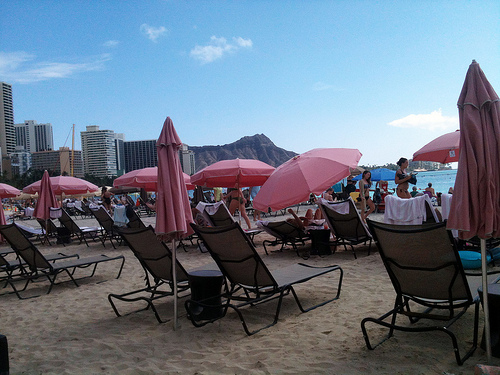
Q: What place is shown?
A: It is a beach.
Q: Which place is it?
A: It is a beach.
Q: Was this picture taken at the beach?
A: Yes, it was taken in the beach.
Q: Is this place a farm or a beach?
A: It is a beach.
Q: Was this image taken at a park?
A: No, the picture was taken in a beach.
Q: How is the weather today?
A: It is clear.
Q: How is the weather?
A: It is clear.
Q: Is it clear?
A: Yes, it is clear.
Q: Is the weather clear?
A: Yes, it is clear.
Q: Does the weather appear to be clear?
A: Yes, it is clear.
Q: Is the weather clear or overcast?
A: It is clear.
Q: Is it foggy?
A: No, it is clear.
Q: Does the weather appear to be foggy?
A: No, it is clear.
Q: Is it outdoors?
A: Yes, it is outdoors.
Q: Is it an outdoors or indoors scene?
A: It is outdoors.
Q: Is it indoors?
A: No, it is outdoors.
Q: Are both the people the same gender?
A: Yes, all the people are female.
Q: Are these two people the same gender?
A: Yes, all the people are female.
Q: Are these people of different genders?
A: No, all the people are female.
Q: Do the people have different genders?
A: No, all the people are female.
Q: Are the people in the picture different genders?
A: No, all the people are female.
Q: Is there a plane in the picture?
A: No, there are no airplanes.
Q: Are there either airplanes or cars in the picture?
A: No, there are no airplanes or cars.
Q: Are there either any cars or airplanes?
A: No, there are no airplanes or cars.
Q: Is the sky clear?
A: Yes, the sky is clear.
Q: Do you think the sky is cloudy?
A: No, the sky is clear.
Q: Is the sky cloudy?
A: No, the sky is clear.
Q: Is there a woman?
A: Yes, there is a woman.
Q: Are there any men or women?
A: Yes, there is a woman.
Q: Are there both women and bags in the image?
A: No, there is a woman but no bags.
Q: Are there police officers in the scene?
A: No, there are no police officers.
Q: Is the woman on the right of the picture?
A: Yes, the woman is on the right of the image.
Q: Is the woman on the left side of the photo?
A: No, the woman is on the right of the image.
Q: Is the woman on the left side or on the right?
A: The woman is on the right of the image.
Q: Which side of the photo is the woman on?
A: The woman is on the right of the image.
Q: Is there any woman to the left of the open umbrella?
A: No, the woman is to the right of the umbrella.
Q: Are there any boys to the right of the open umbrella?
A: No, there is a woman to the right of the umbrella.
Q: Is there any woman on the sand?
A: Yes, there is a woman on the sand.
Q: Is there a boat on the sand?
A: No, there is a woman on the sand.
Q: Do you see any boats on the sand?
A: No, there is a woman on the sand.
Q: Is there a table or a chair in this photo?
A: Yes, there is a chair.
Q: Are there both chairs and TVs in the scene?
A: No, there is a chair but no televisions.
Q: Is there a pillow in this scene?
A: No, there are no pillows.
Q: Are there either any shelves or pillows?
A: No, there are no pillows or shelves.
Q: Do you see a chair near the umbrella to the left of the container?
A: Yes, there is a chair near the umbrella.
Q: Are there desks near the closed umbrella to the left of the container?
A: No, there is a chair near the umbrella.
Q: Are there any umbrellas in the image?
A: Yes, there is an umbrella.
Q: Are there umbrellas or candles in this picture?
A: Yes, there is an umbrella.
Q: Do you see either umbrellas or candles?
A: Yes, there is an umbrella.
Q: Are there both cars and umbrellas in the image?
A: No, there is an umbrella but no cars.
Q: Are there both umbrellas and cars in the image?
A: No, there is an umbrella but no cars.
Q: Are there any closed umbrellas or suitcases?
A: Yes, there is a closed umbrella.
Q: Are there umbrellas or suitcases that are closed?
A: Yes, the umbrella is closed.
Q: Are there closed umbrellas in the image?
A: Yes, there is a closed umbrella.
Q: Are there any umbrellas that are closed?
A: Yes, there is an umbrella that is closed.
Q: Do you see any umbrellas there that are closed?
A: Yes, there is an umbrella that is closed.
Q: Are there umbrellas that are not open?
A: Yes, there is an closed umbrella.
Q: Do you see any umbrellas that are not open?
A: Yes, there is an closed umbrella.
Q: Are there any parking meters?
A: No, there are no parking meters.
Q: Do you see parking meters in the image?
A: No, there are no parking meters.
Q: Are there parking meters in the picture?
A: No, there are no parking meters.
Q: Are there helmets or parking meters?
A: No, there are no parking meters or helmets.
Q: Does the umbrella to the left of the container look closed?
A: Yes, the umbrella is closed.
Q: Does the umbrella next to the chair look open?
A: No, the umbrella is closed.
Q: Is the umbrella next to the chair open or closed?
A: The umbrella is closed.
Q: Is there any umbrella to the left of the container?
A: Yes, there is an umbrella to the left of the container.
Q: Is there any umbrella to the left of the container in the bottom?
A: Yes, there is an umbrella to the left of the container.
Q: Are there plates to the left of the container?
A: No, there is an umbrella to the left of the container.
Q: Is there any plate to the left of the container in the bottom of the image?
A: No, there is an umbrella to the left of the container.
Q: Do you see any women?
A: Yes, there is a woman.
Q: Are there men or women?
A: Yes, there is a woman.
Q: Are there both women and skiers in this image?
A: No, there is a woman but no skiers.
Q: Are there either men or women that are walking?
A: Yes, the woman is walking.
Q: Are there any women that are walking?
A: Yes, there is a woman that is walking.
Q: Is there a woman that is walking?
A: Yes, there is a woman that is walking.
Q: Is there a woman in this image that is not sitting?
A: Yes, there is a woman that is walking.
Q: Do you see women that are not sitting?
A: Yes, there is a woman that is walking .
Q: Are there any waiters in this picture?
A: No, there are no waiters.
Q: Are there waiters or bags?
A: No, there are no waiters or bags.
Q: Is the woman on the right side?
A: Yes, the woman is on the right of the image.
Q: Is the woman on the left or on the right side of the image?
A: The woman is on the right of the image.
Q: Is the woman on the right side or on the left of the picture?
A: The woman is on the right of the image.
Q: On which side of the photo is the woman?
A: The woman is on the right of the image.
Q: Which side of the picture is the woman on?
A: The woman is on the right of the image.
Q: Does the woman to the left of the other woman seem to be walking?
A: Yes, the woman is walking.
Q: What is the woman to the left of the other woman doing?
A: The woman is walking.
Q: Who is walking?
A: The woman is walking.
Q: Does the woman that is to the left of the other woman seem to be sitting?
A: No, the woman is walking.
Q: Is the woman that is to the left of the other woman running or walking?
A: The woman is walking.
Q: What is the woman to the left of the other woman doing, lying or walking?
A: The woman is walking.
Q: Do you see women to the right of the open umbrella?
A: Yes, there is a woman to the right of the umbrella.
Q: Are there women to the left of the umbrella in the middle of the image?
A: No, the woman is to the right of the umbrella.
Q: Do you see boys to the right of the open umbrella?
A: No, there is a woman to the right of the umbrella.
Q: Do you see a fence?
A: No, there are no fences.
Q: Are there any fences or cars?
A: No, there are no fences or cars.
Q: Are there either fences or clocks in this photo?
A: No, there are no clocks or fences.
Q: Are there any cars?
A: No, there are no cars.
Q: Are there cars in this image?
A: No, there are no cars.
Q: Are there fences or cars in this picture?
A: No, there are no cars or fences.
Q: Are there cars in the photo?
A: No, there are no cars.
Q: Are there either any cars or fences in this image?
A: No, there are no cars or fences.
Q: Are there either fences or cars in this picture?
A: No, there are no cars or fences.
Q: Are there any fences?
A: No, there are no fences.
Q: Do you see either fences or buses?
A: No, there are no fences or buses.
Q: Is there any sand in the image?
A: Yes, there is sand.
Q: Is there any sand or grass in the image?
A: Yes, there is sand.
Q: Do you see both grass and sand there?
A: No, there is sand but no grass.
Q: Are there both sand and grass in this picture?
A: No, there is sand but no grass.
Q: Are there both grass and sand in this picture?
A: No, there is sand but no grass.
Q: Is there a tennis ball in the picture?
A: No, there are no tennis balls.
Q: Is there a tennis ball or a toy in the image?
A: No, there are no tennis balls or toys.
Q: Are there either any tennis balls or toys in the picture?
A: No, there are no tennis balls or toys.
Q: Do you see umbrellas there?
A: Yes, there is an umbrella.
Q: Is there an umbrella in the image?
A: Yes, there is an umbrella.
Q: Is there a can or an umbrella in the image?
A: Yes, there is an umbrella.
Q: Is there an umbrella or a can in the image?
A: Yes, there is an umbrella.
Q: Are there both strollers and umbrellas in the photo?
A: No, there is an umbrella but no strollers.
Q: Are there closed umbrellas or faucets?
A: Yes, there is a closed umbrella.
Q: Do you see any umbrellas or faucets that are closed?
A: Yes, the umbrella is closed.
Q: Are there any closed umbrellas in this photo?
A: Yes, there is a closed umbrella.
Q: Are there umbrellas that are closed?
A: Yes, there is an umbrella that is closed.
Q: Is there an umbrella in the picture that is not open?
A: Yes, there is an closed umbrella.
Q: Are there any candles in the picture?
A: No, there are no candles.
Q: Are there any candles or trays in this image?
A: No, there are no candles or trays.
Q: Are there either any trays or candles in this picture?
A: No, there are no candles or trays.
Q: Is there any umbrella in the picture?
A: Yes, there is an umbrella.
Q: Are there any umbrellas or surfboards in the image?
A: Yes, there is an umbrella.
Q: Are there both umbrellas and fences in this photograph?
A: No, there is an umbrella but no fences.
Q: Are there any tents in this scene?
A: No, there are no tents.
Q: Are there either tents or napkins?
A: No, there are no tents or napkins.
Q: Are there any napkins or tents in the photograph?
A: No, there are no tents or napkins.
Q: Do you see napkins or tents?
A: No, there are no tents or napkins.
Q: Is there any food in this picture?
A: No, there is no food.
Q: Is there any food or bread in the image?
A: No, there are no food or breads.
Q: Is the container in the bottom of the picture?
A: Yes, the container is in the bottom of the image.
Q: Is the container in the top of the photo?
A: No, the container is in the bottom of the image.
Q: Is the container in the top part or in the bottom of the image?
A: The container is in the bottom of the image.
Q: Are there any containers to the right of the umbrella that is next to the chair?
A: Yes, there is a container to the right of the umbrella.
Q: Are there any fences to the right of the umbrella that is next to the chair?
A: No, there is a container to the right of the umbrella.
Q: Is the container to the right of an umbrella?
A: Yes, the container is to the right of an umbrella.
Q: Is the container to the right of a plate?
A: No, the container is to the right of an umbrella.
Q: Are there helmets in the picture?
A: No, there are no helmets.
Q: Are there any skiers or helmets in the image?
A: No, there are no helmets or skiers.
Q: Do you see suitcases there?
A: No, there are no suitcases.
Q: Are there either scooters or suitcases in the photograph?
A: No, there are no suitcases or scooters.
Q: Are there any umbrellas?
A: Yes, there is an umbrella.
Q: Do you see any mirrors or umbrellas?
A: Yes, there is an umbrella.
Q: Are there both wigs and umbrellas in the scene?
A: No, there is an umbrella but no wigs.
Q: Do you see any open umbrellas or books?
A: Yes, there is an open umbrella.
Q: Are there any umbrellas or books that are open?
A: Yes, the umbrella is open.